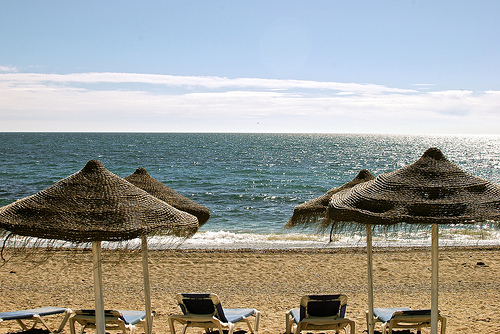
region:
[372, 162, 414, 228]
straw that makes up an umbrella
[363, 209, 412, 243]
the fringe of a beach umbrella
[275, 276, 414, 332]
a row of fold up beach chairs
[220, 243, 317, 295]
a lot of brown beach sand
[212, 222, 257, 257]
waves foaming up on the shore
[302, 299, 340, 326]
the plastic part of a beach chair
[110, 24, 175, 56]
a crisp clear blue sky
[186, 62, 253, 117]
a long line of wispy clouds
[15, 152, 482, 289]
brown umbrellas on beach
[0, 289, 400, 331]
brown chairs on sand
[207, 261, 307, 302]
ground is dark brown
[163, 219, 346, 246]
white waves on water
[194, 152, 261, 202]
water is dark blue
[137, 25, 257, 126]
white and blue sky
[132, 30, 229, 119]
white and layered clouds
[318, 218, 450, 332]
brown poles for umbrellas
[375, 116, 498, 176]
sun shines on water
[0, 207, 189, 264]
long fringes on umbrellas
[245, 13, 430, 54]
Clear blue sky in the distance.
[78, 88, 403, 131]
White clouds fill the sky.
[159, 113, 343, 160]
Where the water and sky meet.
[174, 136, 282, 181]
Deep blue ocean water.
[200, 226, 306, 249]
Small waves come ashore.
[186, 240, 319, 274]
Beach covered with foot prints.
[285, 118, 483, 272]
Beach umbrellas provide shade.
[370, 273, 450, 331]
Blue lounge chair under the umbrella.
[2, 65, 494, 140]
Wispy clouds along the horizon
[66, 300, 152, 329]
Laid back beach chair on empty beach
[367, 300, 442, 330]
Fully reclined beach chair under umbrella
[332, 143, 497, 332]
Large, thatched style beach umbrella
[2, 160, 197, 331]
Large umbrella providing shade on beach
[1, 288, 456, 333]
Group of empty loungers on sunny beach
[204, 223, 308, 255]
Small waves crashing on beach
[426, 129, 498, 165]
Sun brightly reflecting off ocean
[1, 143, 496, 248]
Group of brown umbrellas shading an empty beach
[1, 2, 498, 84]
Blue sky in front of incoming wispy clouds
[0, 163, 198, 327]
this is a shade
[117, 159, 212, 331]
this is a shade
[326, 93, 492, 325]
this is a shade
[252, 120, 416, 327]
this is a shade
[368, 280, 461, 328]
this is a basking bench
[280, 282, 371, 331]
this is a basking bench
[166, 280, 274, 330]
this is a basking bench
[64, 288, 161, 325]
this is a basking bench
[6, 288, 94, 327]
this is a basking bench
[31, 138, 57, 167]
calm waters with very small waves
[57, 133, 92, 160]
calm waters with very small waves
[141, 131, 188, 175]
calm waters with very small waves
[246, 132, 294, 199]
calm waters with very small waves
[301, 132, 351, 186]
calm waters with very small waves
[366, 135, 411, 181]
calm waters with very small waves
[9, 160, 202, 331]
a large open umbrella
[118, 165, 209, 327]
a large open umbrella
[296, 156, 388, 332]
a large open umbrella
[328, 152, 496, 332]
a large open umbrella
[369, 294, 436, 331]
a chair that you sit in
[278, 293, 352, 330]
a chair that you sit in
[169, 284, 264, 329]
a chair that you sit in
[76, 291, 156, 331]
a chair that you sit in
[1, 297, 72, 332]
a chair that you sit in